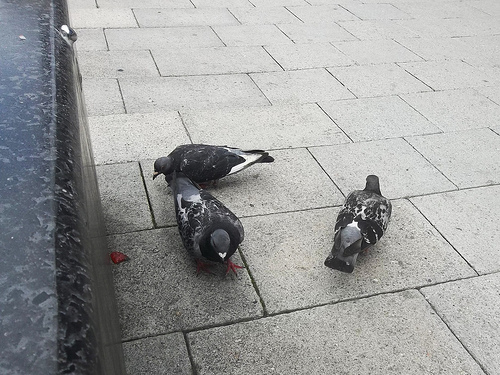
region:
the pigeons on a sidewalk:
[141, 141, 396, 286]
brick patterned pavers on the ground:
[62, 3, 499, 373]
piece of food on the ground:
[107, 246, 134, 268]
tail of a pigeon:
[322, 240, 364, 275]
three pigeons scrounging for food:
[137, 132, 397, 287]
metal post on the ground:
[1, 5, 135, 365]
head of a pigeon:
[147, 151, 172, 186]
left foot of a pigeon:
[224, 258, 245, 282]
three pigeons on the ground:
[134, 132, 403, 286]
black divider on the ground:
[4, 3, 127, 373]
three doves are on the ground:
[106, 20, 407, 287]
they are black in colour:
[141, 55, 387, 316]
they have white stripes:
[133, 117, 382, 280]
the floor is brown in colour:
[218, 25, 345, 126]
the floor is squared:
[136, 23, 336, 116]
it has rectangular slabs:
[187, 45, 364, 120]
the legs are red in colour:
[203, 257, 240, 281]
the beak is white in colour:
[208, 246, 233, 258]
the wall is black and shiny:
[26, 63, 101, 229]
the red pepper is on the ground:
[97, 243, 134, 267]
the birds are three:
[157, 119, 410, 288]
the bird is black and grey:
[169, 175, 262, 285]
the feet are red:
[221, 267, 246, 276]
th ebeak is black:
[219, 252, 228, 266]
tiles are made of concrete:
[255, 285, 369, 352]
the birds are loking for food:
[151, 136, 393, 299]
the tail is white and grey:
[233, 147, 270, 184]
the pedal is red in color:
[111, 248, 136, 271]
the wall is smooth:
[45, 188, 128, 369]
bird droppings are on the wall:
[53, 11, 87, 45]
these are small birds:
[210, 100, 401, 255]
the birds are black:
[183, 85, 329, 245]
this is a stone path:
[151, 276, 235, 366]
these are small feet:
[203, 251, 292, 313]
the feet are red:
[211, 272, 268, 306]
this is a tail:
[242, 130, 289, 170]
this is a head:
[146, 151, 186, 210]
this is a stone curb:
[48, 223, 90, 315]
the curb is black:
[52, 268, 77, 370]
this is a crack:
[189, 309, 231, 364]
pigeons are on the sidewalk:
[138, 106, 402, 297]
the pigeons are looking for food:
[145, 133, 395, 293]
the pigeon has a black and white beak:
[148, 167, 165, 181]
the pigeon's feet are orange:
[196, 254, 251, 284]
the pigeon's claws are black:
[218, 260, 255, 286]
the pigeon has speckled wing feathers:
[325, 185, 396, 244]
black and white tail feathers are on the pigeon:
[232, 142, 278, 179]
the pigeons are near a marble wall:
[0, 83, 412, 300]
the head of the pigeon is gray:
[208, 224, 235, 263]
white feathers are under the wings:
[338, 200, 380, 250]